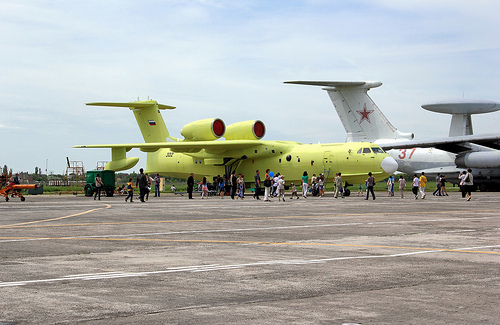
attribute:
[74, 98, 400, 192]
plane — big, grounded, yellow, cargo plane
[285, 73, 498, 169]
plane — white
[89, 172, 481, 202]
people — walking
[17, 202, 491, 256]
tarmac — gray, concrete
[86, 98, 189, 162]
tail — large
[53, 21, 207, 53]
clouds — thin, white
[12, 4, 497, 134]
sky — blue, hazy, brighty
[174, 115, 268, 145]
engines — red